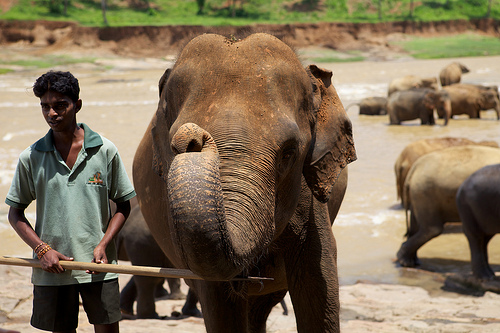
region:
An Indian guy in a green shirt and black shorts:
[2, 70, 137, 331]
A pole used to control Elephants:
[0, 253, 278, 293]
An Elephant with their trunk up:
[130, 32, 372, 332]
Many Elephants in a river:
[357, 62, 499, 129]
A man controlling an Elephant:
[7, 32, 377, 331]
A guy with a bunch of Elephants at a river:
[7, 32, 498, 330]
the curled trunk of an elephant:
[172, 121, 279, 276]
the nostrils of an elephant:
[166, 130, 202, 152]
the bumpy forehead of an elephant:
[182, 31, 296, 106]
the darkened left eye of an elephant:
[277, 126, 302, 166]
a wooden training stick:
[0, 253, 272, 277]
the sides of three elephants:
[393, 135, 498, 275]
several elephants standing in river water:
[346, 59, 498, 123]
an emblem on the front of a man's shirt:
[87, 170, 104, 185]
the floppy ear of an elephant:
[304, 63, 355, 204]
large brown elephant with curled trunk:
[127, 27, 362, 332]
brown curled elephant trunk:
[157, 120, 276, 283]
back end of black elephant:
[455, 159, 499, 285]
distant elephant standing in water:
[382, 84, 453, 134]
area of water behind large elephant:
[3, 50, 498, 326]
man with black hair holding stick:
[2, 64, 139, 331]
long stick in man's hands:
[2, 241, 282, 299]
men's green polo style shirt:
[3, 123, 142, 298]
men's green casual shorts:
[17, 273, 128, 330]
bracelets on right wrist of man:
[25, 238, 55, 258]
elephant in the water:
[438, 57, 470, 87]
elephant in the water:
[391, 74, 437, 95]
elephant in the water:
[447, 78, 497, 91]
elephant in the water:
[441, 85, 497, 118]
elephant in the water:
[389, 90, 450, 125]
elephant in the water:
[349, 93, 391, 118]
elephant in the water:
[389, 135, 495, 204]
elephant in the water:
[398, 150, 496, 267]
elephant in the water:
[457, 160, 497, 282]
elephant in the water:
[113, 215, 201, 319]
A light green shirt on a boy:
[3, 122, 134, 299]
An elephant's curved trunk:
[167, 122, 262, 272]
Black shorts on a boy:
[27, 274, 115, 331]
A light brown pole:
[0, 253, 274, 286]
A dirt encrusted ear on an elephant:
[300, 61, 355, 197]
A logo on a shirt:
[87, 171, 105, 188]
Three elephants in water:
[393, 133, 498, 286]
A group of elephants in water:
[340, 58, 498, 119]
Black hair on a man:
[28, 68, 78, 93]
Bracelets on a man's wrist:
[29, 241, 53, 255]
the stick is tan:
[71, 255, 241, 286]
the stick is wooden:
[70, 258, 242, 283]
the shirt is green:
[18, 152, 125, 285]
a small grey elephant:
[135, 31, 356, 331]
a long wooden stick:
[1, 253, 271, 283]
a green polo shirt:
[3, 121, 136, 282]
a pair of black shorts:
[31, 278, 121, 328]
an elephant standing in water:
[385, 88, 452, 127]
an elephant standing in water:
[439, 85, 499, 122]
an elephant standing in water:
[437, 62, 468, 85]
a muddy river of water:
[2, 59, 499, 297]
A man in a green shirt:
[22, 74, 120, 310]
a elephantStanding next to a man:
[118, 55, 343, 270]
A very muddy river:
[325, 186, 410, 276]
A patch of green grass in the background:
[401, 33, 473, 68]